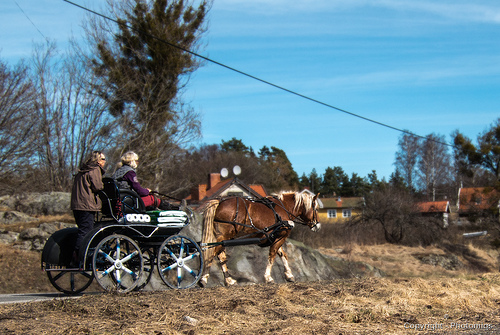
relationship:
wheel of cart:
[92, 235, 144, 296] [37, 208, 202, 290]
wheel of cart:
[158, 231, 208, 291] [40, 176, 321, 294]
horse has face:
[198, 186, 322, 286] [298, 185, 321, 231]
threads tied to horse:
[208, 192, 312, 244] [198, 186, 322, 286]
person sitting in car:
[103, 147, 182, 212] [19, 200, 210, 300]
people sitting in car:
[73, 149, 108, 268] [19, 200, 210, 300]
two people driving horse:
[67, 145, 160, 215] [201, 177, 330, 284]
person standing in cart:
[110, 150, 190, 212] [40, 176, 321, 294]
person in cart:
[110, 150, 190, 212] [40, 176, 321, 294]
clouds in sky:
[285, 19, 415, 62] [0, 1, 497, 191]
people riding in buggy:
[73, 149, 108, 268] [32, 128, 340, 327]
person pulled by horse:
[110, 150, 190, 212] [164, 177, 361, 324]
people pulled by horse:
[73, 149, 108, 268] [164, 177, 361, 324]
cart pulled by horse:
[32, 194, 207, 301] [199, 175, 332, 292]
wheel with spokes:
[89, 236, 162, 299] [96, 249, 142, 276]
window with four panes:
[326, 207, 338, 219] [328, 210, 335, 217]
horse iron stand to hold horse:
[198, 186, 322, 286] [167, 126, 335, 292]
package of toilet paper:
[117, 205, 151, 258] [117, 210, 159, 226]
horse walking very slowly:
[198, 186, 322, 286] [87, 194, 265, 311]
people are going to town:
[73, 149, 108, 268] [186, 161, 498, 229]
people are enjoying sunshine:
[73, 149, 148, 196] [140, 49, 434, 233]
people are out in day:
[73, 149, 108, 268] [52, 68, 299, 334]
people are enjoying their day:
[73, 149, 108, 268] [23, 165, 178, 335]